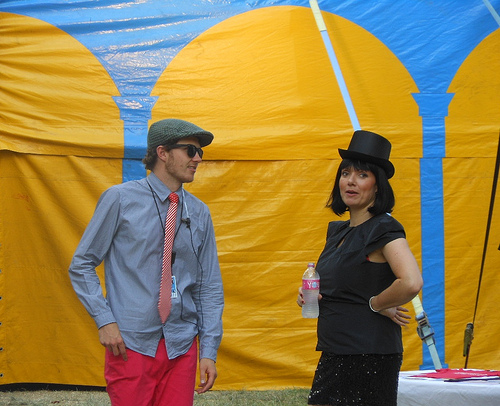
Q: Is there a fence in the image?
A: No, there are no fences.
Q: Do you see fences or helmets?
A: No, there are no fences or helmets.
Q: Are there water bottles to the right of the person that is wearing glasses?
A: Yes, there is a water bottle to the right of the person.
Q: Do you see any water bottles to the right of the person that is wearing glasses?
A: Yes, there is a water bottle to the right of the person.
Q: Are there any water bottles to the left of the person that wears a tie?
A: No, the water bottle is to the right of the person.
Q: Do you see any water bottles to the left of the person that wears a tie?
A: No, the water bottle is to the right of the person.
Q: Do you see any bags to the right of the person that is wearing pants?
A: No, there is a water bottle to the right of the person.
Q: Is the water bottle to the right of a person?
A: Yes, the water bottle is to the right of a person.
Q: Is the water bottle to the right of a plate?
A: No, the water bottle is to the right of a person.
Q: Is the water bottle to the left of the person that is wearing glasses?
A: No, the water bottle is to the right of the person.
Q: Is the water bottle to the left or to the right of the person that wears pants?
A: The water bottle is to the right of the person.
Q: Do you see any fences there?
A: No, there are no fences.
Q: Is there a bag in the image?
A: No, there are no bags.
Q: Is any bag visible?
A: No, there are no bags.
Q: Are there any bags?
A: No, there are no bags.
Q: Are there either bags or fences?
A: No, there are no bags or fences.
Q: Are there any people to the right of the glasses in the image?
A: Yes, there is a person to the right of the glasses.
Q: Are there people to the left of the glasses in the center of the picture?
A: No, the person is to the right of the glasses.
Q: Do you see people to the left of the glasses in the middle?
A: No, the person is to the right of the glasses.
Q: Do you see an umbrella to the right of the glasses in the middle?
A: No, there is a person to the right of the glasses.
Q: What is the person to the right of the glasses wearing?
A: The person is wearing a shirt.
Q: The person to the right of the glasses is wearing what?
A: The person is wearing a shirt.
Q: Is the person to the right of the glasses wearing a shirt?
A: Yes, the person is wearing a shirt.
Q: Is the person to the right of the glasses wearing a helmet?
A: No, the person is wearing a shirt.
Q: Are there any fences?
A: No, there are no fences.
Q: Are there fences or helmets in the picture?
A: No, there are no fences or helmets.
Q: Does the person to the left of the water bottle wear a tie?
A: Yes, the person wears a tie.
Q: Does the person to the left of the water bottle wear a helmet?
A: No, the person wears a tie.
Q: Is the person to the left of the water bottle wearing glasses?
A: Yes, the person is wearing glasses.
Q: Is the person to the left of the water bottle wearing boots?
A: No, the person is wearing glasses.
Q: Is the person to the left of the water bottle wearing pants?
A: Yes, the person is wearing pants.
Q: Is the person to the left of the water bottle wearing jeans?
A: No, the person is wearing pants.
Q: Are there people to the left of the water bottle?
A: Yes, there is a person to the left of the water bottle.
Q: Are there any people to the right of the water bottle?
A: No, the person is to the left of the water bottle.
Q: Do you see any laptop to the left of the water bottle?
A: No, there is a person to the left of the water bottle.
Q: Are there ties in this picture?
A: Yes, there is a tie.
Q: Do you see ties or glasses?
A: Yes, there is a tie.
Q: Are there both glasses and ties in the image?
A: Yes, there are both a tie and glasses.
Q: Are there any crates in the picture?
A: No, there are no crates.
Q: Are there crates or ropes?
A: No, there are no crates or ropes.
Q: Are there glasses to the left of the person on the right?
A: Yes, there are glasses to the left of the person.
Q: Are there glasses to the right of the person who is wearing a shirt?
A: No, the glasses are to the left of the person.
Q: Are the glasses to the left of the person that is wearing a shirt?
A: Yes, the glasses are to the left of the person.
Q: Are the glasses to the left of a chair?
A: No, the glasses are to the left of the person.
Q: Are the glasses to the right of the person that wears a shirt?
A: No, the glasses are to the left of the person.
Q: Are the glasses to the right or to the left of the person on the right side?
A: The glasses are to the left of the person.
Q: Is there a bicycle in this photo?
A: No, there are no bicycles.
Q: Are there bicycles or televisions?
A: No, there are no bicycles or televisions.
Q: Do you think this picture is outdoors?
A: Yes, the picture is outdoors.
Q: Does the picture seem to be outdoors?
A: Yes, the picture is outdoors.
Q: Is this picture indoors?
A: No, the picture is outdoors.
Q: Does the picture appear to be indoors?
A: No, the picture is outdoors.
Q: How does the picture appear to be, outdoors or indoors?
A: The picture is outdoors.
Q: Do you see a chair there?
A: No, there are no chairs.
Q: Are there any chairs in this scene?
A: No, there are no chairs.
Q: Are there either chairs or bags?
A: No, there are no chairs or bags.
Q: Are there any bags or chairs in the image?
A: No, there are no chairs or bags.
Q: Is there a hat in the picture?
A: Yes, there is a hat.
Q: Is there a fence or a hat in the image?
A: Yes, there is a hat.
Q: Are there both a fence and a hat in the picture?
A: No, there is a hat but no fences.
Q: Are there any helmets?
A: No, there are no helmets.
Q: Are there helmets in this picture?
A: No, there are no helmets.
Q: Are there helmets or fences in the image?
A: No, there are no helmets or fences.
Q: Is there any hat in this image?
A: Yes, there is a hat.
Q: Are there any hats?
A: Yes, there is a hat.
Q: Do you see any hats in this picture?
A: Yes, there is a hat.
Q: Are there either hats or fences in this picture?
A: Yes, there is a hat.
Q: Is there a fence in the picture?
A: No, there are no fences.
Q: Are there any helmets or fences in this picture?
A: No, there are no fences or helmets.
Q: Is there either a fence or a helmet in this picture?
A: No, there are no fences or helmets.